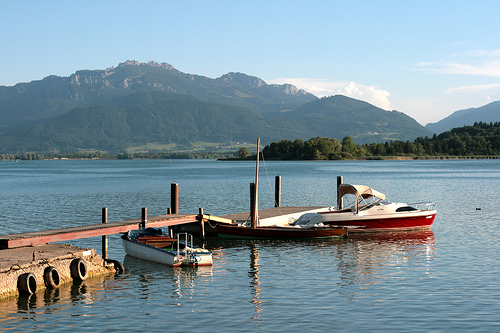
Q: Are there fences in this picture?
A: No, there are no fences.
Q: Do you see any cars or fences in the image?
A: No, there are no fences or cars.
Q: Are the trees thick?
A: Yes, the trees are thick.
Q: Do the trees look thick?
A: Yes, the trees are thick.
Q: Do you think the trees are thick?
A: Yes, the trees are thick.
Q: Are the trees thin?
A: No, the trees are thick.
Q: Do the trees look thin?
A: No, the trees are thick.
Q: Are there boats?
A: Yes, there is a boat.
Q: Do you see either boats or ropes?
A: Yes, there is a boat.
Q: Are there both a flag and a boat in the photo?
A: No, there is a boat but no flags.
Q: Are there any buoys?
A: No, there are no buoys.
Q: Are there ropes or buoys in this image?
A: No, there are no buoys or ropes.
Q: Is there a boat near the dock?
A: Yes, there is a boat near the dock.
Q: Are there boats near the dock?
A: Yes, there is a boat near the dock.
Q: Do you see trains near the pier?
A: No, there is a boat near the pier.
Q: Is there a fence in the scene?
A: No, there are no fences.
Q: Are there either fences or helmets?
A: No, there are no fences or helmets.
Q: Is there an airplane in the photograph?
A: No, there are no airplanes.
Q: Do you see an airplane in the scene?
A: No, there are no airplanes.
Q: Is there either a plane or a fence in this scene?
A: No, there are no airplanes or fences.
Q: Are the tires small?
A: Yes, the tires are small.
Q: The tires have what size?
A: The tires are small.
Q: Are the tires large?
A: No, the tires are small.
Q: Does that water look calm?
A: Yes, the water is calm.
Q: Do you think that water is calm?
A: Yes, the water is calm.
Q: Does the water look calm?
A: Yes, the water is calm.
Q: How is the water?
A: The water is calm.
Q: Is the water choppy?
A: No, the water is calm.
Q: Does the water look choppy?
A: No, the water is calm.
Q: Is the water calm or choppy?
A: The water is calm.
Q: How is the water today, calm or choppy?
A: The water is calm.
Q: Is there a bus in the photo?
A: No, there are no buses.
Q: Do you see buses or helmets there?
A: No, there are no buses or helmets.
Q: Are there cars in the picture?
A: No, there are no cars.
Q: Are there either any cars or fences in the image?
A: No, there are no cars or fences.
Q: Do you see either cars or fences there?
A: No, there are no cars or fences.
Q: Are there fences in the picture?
A: No, there are no fences.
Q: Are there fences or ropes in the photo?
A: No, there are no fences or ropes.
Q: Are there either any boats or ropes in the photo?
A: Yes, there is a boat.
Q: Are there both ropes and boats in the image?
A: No, there is a boat but no ropes.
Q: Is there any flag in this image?
A: No, there are no flags.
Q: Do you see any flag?
A: No, there are no flags.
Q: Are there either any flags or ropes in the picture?
A: No, there are no flags or ropes.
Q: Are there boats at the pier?
A: Yes, there is a boat at the pier.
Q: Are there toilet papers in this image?
A: No, there are no toilet papers.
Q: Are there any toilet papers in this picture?
A: No, there are no toilet papers.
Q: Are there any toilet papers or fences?
A: No, there are no toilet papers or fences.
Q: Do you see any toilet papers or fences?
A: No, there are no toilet papers or fences.